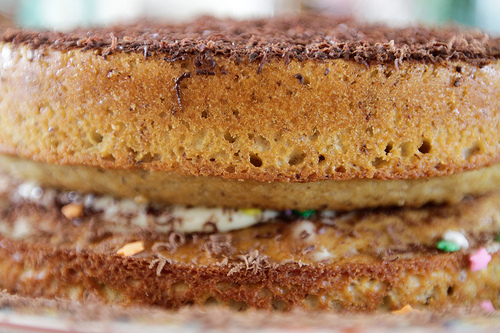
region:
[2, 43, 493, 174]
brown edge of a cake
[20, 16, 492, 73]
dark brown grated chocolate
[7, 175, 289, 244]
cream filling of cake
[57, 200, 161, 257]
small orange confetti in filling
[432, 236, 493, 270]
green and pink confetti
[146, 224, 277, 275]
grated chocolate between layers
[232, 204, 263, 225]
yellow bits in cream filling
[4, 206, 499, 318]
lower cake layer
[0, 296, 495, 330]
edge of plate holding cakes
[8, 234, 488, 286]
brown crispy cake edge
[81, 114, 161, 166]
bread has holes in it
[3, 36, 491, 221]
the cake is light brown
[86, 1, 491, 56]
cake is dark brown on top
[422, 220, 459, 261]
green sprinkle on cake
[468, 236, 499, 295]
pink sprinkle on cake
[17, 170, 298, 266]
icing in between 2 cakes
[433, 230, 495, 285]
sprinkles in shapes of stars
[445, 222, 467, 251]
the sprinkle is white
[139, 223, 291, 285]
coconut flakes on the cake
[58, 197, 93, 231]
the sprinkle is orange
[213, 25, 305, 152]
edge of a cake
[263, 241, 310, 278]
part of a cake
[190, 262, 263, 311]
edge of a cake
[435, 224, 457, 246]
part of a cream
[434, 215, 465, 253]
part of a cream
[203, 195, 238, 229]
part of a creram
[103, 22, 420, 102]
top crust of dessert cake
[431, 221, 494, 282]
three dessert decoration starts pink green white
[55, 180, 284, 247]
cream filling of dessert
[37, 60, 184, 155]
golden crust of dessert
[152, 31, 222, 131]
frizzle brown crust of dessert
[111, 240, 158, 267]
orange star dessert decoration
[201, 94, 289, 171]
spongy holes in dessert cake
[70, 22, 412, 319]
dessert cake golden brown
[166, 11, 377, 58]
top crust of dessert cake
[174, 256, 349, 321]
bottom crust of dessert cake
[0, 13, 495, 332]
a golden brown layer cake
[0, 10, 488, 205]
the top layer of a cake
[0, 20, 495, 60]
toasty crusty chocolate crust on cake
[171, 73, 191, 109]
a chocolate shaving on a cake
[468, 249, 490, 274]
a pink star sprinkle on a cake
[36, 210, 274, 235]
cream filling in a layer cake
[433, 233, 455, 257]
green star sprinkle on a cake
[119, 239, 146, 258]
orange star sprinkle on a cake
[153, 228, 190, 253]
a chocolate shaving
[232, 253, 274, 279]
chocolate shavings